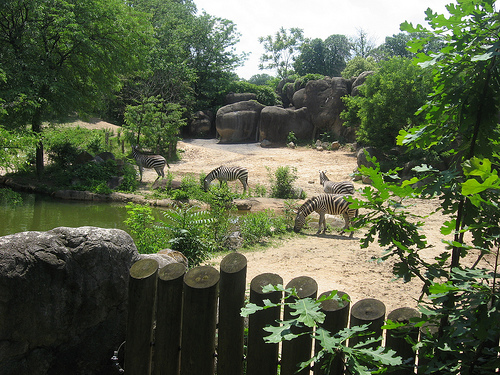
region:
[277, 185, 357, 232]
zebra near a lake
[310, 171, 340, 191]
zebra near a lake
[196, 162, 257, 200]
zebra near a lake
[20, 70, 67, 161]
tree near a lake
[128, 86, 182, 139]
tree near a lake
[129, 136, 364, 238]
four zebras in an enclouse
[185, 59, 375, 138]
rock wall in the enclosure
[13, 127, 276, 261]
plants growing around pond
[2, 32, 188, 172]
tree growing beside pond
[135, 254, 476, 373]
log fence in the foreground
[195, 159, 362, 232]
zebra grazing in the enclosure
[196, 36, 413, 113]
trees behind rock wall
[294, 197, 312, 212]
white and black mane on the zebra's neck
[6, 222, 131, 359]
rock wall next to the log fence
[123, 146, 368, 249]
Group of zebras near water.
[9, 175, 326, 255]
Body of green colored water.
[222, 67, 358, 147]
Large boulder shaped wall.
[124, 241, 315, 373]
Wood posts forming wall.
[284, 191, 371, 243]
Zebra grazing on grass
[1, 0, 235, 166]
Large green trees in enclosure.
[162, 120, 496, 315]
Large sandy area in enclosure.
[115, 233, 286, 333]
Wood post ends cut at an angle.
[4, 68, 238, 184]
Small dirt hill in enclosure.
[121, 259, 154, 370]
brown wooden fence post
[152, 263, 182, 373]
brown wooden fence post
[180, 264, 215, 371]
brown wooden fence post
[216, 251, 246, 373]
brown wooden fence post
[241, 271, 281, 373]
brown wooden fence post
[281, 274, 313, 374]
brown wooden fence post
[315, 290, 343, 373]
brown wooden fence post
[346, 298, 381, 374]
brown wooden fence post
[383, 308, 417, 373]
brown wooden fence post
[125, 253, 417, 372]
brown wooden fence posts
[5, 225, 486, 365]
rocks and row of logs forming barrier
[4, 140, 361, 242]
zebras standing near edge of pond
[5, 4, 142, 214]
tree and bushes at edge of pond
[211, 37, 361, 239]
curved and large gray boulders behind zebras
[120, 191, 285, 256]
varied growth along edge of pond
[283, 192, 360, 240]
zebra grazing on patch of grass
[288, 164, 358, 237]
zebra standing in back of another zebra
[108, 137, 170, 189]
zebra behind bush in shade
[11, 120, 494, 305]
flat dirt covering zebra enclosure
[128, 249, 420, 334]
flat and round surface of cut logs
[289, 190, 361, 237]
giraffe grazing in zoo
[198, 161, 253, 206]
giraffe grazing in zoo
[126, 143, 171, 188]
giraffe standing in zoo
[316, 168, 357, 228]
giraffe standing in zoo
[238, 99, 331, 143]
rock wall behind the animals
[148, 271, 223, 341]
wooden poles acting as a fence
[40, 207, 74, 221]
drinking water for the animals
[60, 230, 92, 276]
rock beside the poles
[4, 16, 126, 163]
large tree beside the water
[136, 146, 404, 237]
zebra'a grazing the land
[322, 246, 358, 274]
dirt the zebra's are on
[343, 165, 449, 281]
leaves coming from the trees